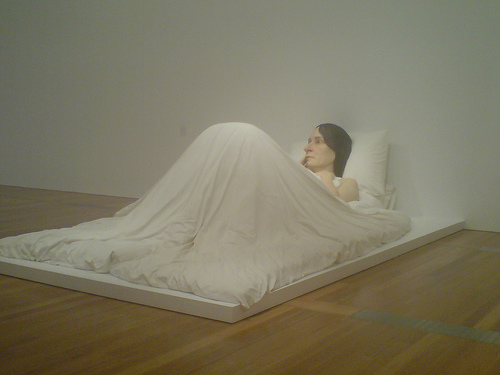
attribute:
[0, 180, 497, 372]
floor — wood, hardwood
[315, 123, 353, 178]
hair — brunette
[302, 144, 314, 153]
nose — large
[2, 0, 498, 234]
wall — white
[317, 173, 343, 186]
top — white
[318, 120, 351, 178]
hair — dark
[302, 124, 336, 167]
face — pale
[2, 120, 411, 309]
bedding — wrinkled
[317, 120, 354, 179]
hair — brown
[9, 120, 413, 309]
sheet — white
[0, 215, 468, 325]
square — white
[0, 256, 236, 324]
edge — white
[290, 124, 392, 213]
pillow — white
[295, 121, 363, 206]
woman — sculptured